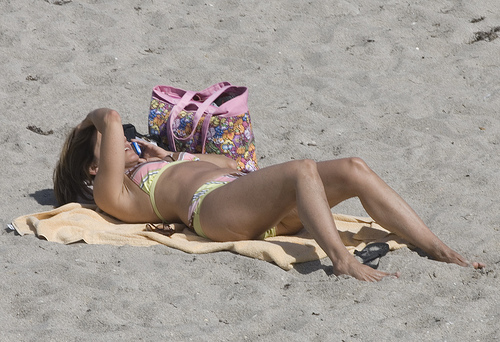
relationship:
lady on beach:
[74, 121, 451, 297] [8, 2, 498, 338]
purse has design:
[158, 88, 249, 150] [158, 107, 242, 150]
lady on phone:
[74, 121, 451, 297] [121, 121, 152, 163]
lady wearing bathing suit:
[74, 121, 451, 297] [129, 152, 199, 216]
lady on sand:
[74, 121, 451, 297] [34, 240, 271, 341]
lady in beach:
[74, 121, 451, 297] [8, 2, 498, 338]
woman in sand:
[57, 113, 392, 242] [34, 240, 271, 341]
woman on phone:
[57, 113, 392, 242] [121, 121, 152, 163]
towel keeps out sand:
[67, 213, 287, 260] [34, 240, 271, 341]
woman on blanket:
[57, 113, 392, 242] [10, 202, 354, 277]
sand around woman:
[34, 240, 271, 341] [57, 113, 392, 242]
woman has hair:
[57, 113, 392, 242] [52, 135, 93, 212]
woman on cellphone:
[57, 113, 392, 242] [124, 144, 147, 157]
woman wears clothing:
[57, 113, 392, 242] [138, 148, 189, 196]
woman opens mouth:
[57, 113, 392, 242] [123, 146, 133, 157]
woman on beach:
[57, 113, 392, 242] [8, 2, 498, 338]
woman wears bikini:
[57, 113, 392, 242] [197, 172, 227, 220]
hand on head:
[71, 107, 108, 143] [68, 108, 135, 187]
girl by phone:
[74, 121, 451, 297] [121, 121, 152, 163]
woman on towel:
[57, 113, 392, 242] [67, 213, 287, 260]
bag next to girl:
[158, 88, 249, 150] [74, 121, 451, 297]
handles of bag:
[170, 81, 211, 165] [158, 88, 249, 150]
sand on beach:
[34, 240, 271, 341] [8, 2, 498, 338]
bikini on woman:
[197, 172, 227, 220] [57, 113, 392, 242]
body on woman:
[122, 153, 277, 235] [57, 113, 392, 242]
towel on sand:
[67, 213, 287, 260] [34, 240, 271, 341]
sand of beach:
[34, 240, 271, 341] [8, 2, 498, 338]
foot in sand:
[335, 248, 390, 288] [34, 240, 271, 341]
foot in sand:
[425, 235, 490, 281] [34, 240, 271, 341]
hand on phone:
[136, 139, 184, 163] [121, 121, 152, 163]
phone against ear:
[121, 121, 152, 163] [120, 131, 133, 142]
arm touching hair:
[75, 107, 144, 194] [52, 135, 93, 212]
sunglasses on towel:
[132, 213, 178, 234] [67, 213, 287, 260]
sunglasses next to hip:
[132, 213, 178, 234] [192, 195, 240, 242]